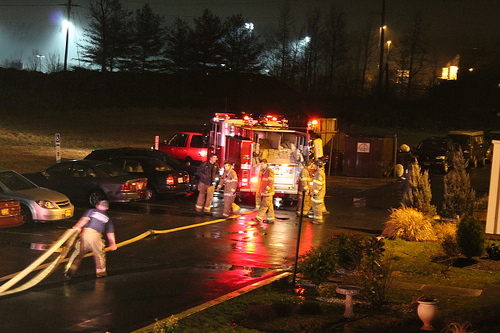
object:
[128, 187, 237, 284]
hose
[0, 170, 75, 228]
cars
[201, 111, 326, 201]
truck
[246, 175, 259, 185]
light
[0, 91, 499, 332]
ground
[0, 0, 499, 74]
sky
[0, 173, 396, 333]
street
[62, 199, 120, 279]
fighter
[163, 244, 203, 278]
bath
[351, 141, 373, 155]
sign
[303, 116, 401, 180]
dumpster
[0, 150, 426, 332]
road